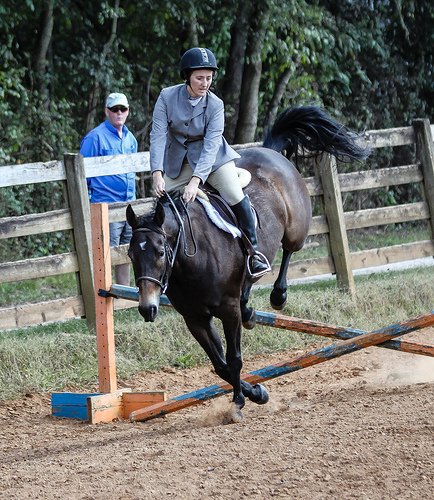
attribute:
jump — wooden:
[51, 202, 432, 421]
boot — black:
[225, 192, 267, 273]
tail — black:
[264, 97, 374, 172]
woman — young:
[131, 81, 266, 222]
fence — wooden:
[0, 119, 432, 347]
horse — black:
[125, 132, 375, 442]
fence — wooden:
[310, 125, 431, 270]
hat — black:
[177, 45, 217, 84]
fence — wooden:
[6, 113, 432, 329]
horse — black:
[116, 99, 381, 425]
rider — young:
[148, 38, 272, 287]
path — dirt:
[233, 430, 377, 492]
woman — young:
[141, 44, 268, 275]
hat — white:
[105, 90, 129, 109]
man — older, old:
[78, 90, 137, 285]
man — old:
[93, 42, 287, 211]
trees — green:
[140, 1, 402, 126]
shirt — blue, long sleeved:
[72, 123, 150, 202]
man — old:
[73, 91, 141, 288]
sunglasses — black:
[108, 106, 129, 113]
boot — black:
[221, 190, 320, 285]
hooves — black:
[216, 287, 290, 429]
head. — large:
[119, 202, 182, 323]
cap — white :
[102, 92, 129, 111]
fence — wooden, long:
[0, 145, 430, 344]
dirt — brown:
[195, 396, 243, 427]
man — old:
[80, 91, 131, 311]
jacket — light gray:
[150, 83, 236, 185]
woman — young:
[149, 54, 268, 282]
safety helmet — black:
[178, 44, 219, 64]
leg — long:
[203, 159, 259, 256]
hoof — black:
[225, 404, 247, 418]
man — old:
[78, 93, 134, 301]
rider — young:
[147, 59, 262, 276]